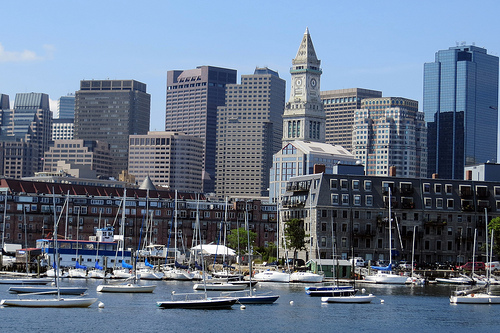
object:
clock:
[310, 78, 317, 87]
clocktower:
[280, 26, 325, 149]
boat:
[304, 286, 354, 295]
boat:
[155, 299, 239, 308]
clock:
[295, 78, 317, 87]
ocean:
[0, 275, 499, 332]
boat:
[321, 296, 376, 303]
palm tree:
[225, 226, 260, 266]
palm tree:
[281, 216, 310, 272]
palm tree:
[478, 216, 500, 263]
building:
[269, 140, 365, 205]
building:
[276, 164, 500, 272]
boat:
[192, 284, 248, 290]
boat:
[449, 293, 499, 304]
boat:
[435, 275, 499, 284]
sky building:
[0, 0, 498, 195]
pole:
[53, 186, 61, 299]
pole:
[120, 187, 126, 270]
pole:
[174, 189, 178, 269]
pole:
[388, 187, 392, 271]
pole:
[472, 228, 477, 281]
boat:
[364, 273, 406, 284]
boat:
[211, 281, 258, 287]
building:
[213, 66, 286, 201]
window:
[238, 100, 242, 102]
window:
[248, 117, 252, 119]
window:
[257, 104, 261, 107]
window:
[258, 86, 262, 88]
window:
[231, 183, 235, 185]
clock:
[295, 79, 303, 87]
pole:
[196, 215, 207, 299]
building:
[0, 175, 276, 264]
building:
[352, 97, 428, 179]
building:
[319, 87, 382, 154]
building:
[281, 26, 327, 143]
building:
[127, 131, 202, 193]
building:
[74, 77, 150, 180]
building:
[42, 139, 113, 180]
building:
[0, 92, 53, 180]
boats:
[0, 262, 500, 309]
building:
[423, 41, 500, 182]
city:
[2, 27, 499, 285]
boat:
[45, 268, 202, 280]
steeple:
[292, 26, 321, 66]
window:
[320, 209, 328, 217]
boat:
[209, 296, 280, 304]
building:
[165, 65, 236, 194]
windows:
[184, 98, 188, 101]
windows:
[200, 111, 205, 114]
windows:
[183, 113, 188, 116]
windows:
[190, 97, 194, 99]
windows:
[220, 113, 224, 115]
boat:
[0, 298, 99, 308]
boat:
[96, 283, 157, 292]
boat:
[243, 269, 289, 283]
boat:
[287, 270, 323, 283]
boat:
[8, 287, 88, 295]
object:
[155, 189, 280, 308]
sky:
[0, 0, 499, 113]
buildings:
[0, 27, 500, 260]